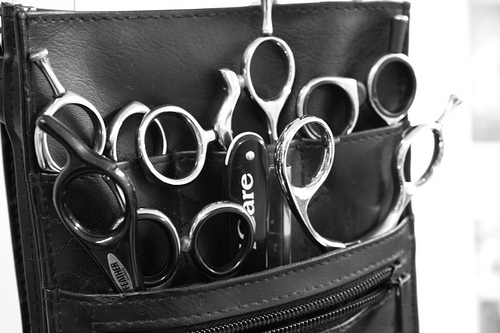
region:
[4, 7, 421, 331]
black leather scissors holder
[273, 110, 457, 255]
shiny silver metal scissors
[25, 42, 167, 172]
shiny silver metal scissors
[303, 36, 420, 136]
shiny silver metal scissors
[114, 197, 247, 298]
shiny black metal scissors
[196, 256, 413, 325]
zipper on black leather object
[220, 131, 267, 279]
black and white object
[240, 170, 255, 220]
letter in white text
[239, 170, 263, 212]
white "are" showing on object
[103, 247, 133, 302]
silver and black logo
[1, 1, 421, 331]
the case is black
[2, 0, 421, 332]
the case is leather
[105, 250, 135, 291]
the handle says feather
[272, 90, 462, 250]
the handles are wide apart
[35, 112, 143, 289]
the handle is black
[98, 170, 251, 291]
the handles are silver and black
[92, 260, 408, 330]
the case has a zipper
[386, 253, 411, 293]
the zipper is black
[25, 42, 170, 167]
the silver handles are behind the black one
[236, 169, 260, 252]
the handle says care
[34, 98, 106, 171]
silver finger whole on scissors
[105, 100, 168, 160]
silver finger whole on scissors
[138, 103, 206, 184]
silver finger whole on scissors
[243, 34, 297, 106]
silver finger whole on scissors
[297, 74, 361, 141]
silver finger whole on scissors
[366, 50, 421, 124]
silver finger whole on scissors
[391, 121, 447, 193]
silver finger whole on scissors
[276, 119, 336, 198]
silver finger whole on scissors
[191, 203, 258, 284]
silver finger whole on scissors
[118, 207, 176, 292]
silver finger whole on scissors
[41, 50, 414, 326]
scissors in a pouch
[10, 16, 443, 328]
scissors in a bag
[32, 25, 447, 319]
a bag with scissors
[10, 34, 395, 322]
a black bag with scissors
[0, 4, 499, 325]
a black pouch with scissors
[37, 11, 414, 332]
scissors in a black bag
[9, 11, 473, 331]
scissors in a black puch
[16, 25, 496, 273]
multiple pairs of scissors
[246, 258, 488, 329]
a bag with a zipper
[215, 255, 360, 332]
a zipper on a bag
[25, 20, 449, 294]
Scciors are in the shot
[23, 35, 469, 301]
Grey and black metal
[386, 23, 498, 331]
The background is blurry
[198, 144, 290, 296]
Words on the siccors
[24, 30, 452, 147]
Only silver in the shot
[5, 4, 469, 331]
This is a black bag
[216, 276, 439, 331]
Bag is open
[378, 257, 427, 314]
Zipper is at the edge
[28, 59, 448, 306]
Only two pouches